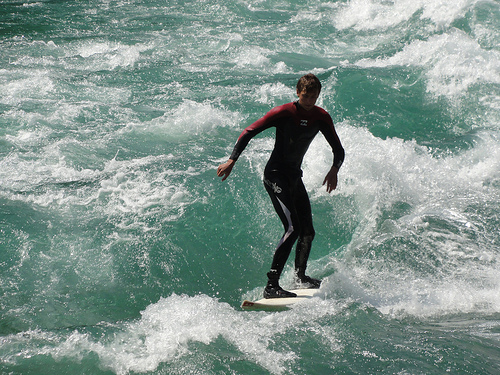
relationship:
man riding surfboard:
[215, 71, 347, 300] [241, 273, 328, 333]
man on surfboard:
[215, 71, 347, 300] [241, 273, 328, 333]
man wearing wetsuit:
[215, 71, 347, 300] [227, 107, 337, 285]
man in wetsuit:
[215, 71, 347, 300] [227, 107, 337, 285]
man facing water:
[215, 71, 347, 300] [2, 2, 495, 369]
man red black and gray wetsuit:
[215, 71, 347, 300] [227, 107, 337, 285]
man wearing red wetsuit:
[215, 71, 347, 300] [227, 107, 337, 285]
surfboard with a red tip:
[241, 273, 328, 333] [238, 298, 255, 311]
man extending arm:
[215, 71, 347, 300] [214, 99, 279, 183]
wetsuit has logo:
[227, 107, 337, 285] [299, 118, 312, 127]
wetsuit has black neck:
[227, 107, 337, 285] [292, 99, 321, 115]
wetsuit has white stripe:
[227, 107, 337, 285] [267, 187, 296, 271]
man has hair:
[215, 71, 347, 300] [294, 72, 325, 97]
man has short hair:
[215, 71, 347, 300] [294, 72, 325, 97]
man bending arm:
[215, 71, 347, 300] [214, 99, 279, 183]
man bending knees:
[215, 71, 347, 300] [276, 224, 321, 243]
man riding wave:
[215, 71, 347, 300] [119, 180, 495, 356]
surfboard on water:
[241, 273, 328, 333] [2, 2, 495, 369]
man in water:
[215, 71, 347, 300] [2, 2, 495, 369]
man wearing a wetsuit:
[215, 71, 347, 300] [227, 107, 337, 285]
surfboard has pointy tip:
[241, 273, 328, 333] [238, 298, 255, 311]